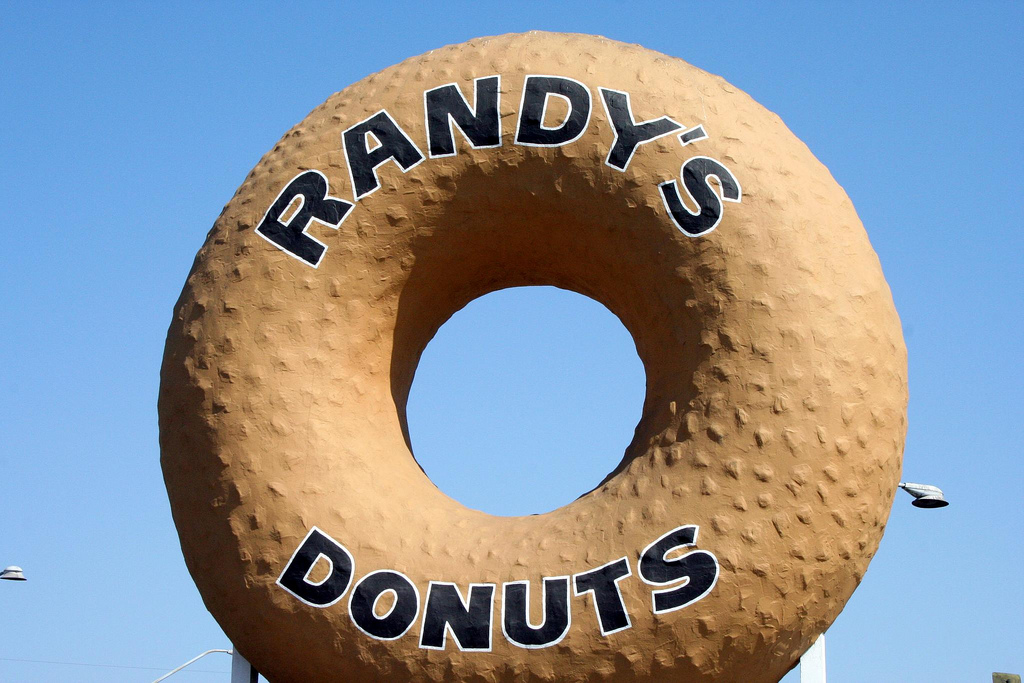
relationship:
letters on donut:
[255, 73, 740, 660] [156, 26, 905, 681]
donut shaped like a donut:
[156, 25, 905, 683] [156, 26, 905, 681]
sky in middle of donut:
[403, 283, 647, 519] [156, 25, 905, 683]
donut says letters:
[156, 25, 905, 683] [255, 73, 740, 660]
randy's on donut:
[251, 73, 738, 267] [156, 25, 905, 683]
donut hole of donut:
[405, 284, 645, 520] [156, 26, 905, 681]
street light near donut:
[1, 563, 28, 584] [156, 26, 905, 681]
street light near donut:
[895, 474, 950, 509] [156, 26, 905, 681]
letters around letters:
[255, 73, 740, 660] [255, 73, 740, 660]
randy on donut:
[254, 73, 684, 268] [156, 26, 905, 681]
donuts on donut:
[277, 524, 717, 652] [156, 26, 905, 681]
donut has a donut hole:
[156, 26, 905, 681] [405, 284, 645, 520]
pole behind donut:
[227, 644, 257, 682] [156, 26, 905, 681]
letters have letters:
[255, 73, 740, 653] [255, 73, 740, 660]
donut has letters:
[156, 26, 905, 681] [255, 73, 740, 653]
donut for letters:
[156, 25, 905, 683] [255, 73, 740, 660]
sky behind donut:
[403, 283, 647, 519] [156, 26, 905, 681]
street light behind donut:
[1, 563, 28, 584] [156, 26, 905, 681]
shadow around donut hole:
[390, 147, 731, 521] [405, 284, 645, 520]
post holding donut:
[797, 628, 824, 681] [156, 25, 905, 683]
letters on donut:
[255, 73, 740, 653] [156, 25, 905, 683]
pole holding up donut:
[227, 644, 257, 682] [156, 26, 905, 681]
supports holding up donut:
[229, 627, 823, 682] [156, 26, 905, 681]